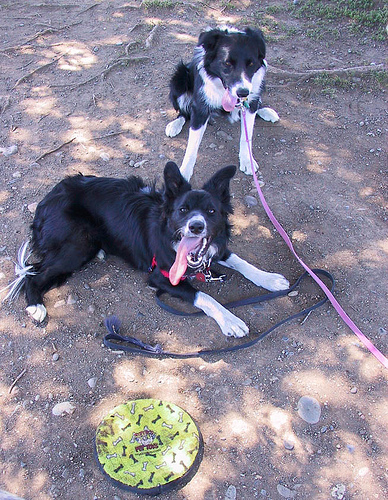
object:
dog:
[165, 26, 280, 180]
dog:
[1, 161, 290, 339]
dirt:
[1, 0, 387, 498]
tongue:
[168, 236, 201, 286]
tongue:
[221, 88, 237, 112]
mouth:
[225, 86, 246, 108]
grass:
[367, 0, 387, 21]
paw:
[223, 316, 251, 338]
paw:
[268, 273, 290, 293]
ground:
[349, 113, 369, 142]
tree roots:
[146, 20, 163, 47]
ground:
[0, 0, 388, 499]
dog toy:
[96, 398, 201, 491]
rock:
[52, 401, 76, 415]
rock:
[298, 395, 321, 424]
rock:
[224, 485, 237, 500]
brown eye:
[226, 62, 232, 66]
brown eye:
[248, 62, 254, 66]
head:
[196, 27, 265, 112]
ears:
[163, 161, 192, 206]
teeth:
[187, 237, 207, 265]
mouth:
[181, 233, 212, 271]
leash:
[242, 106, 388, 368]